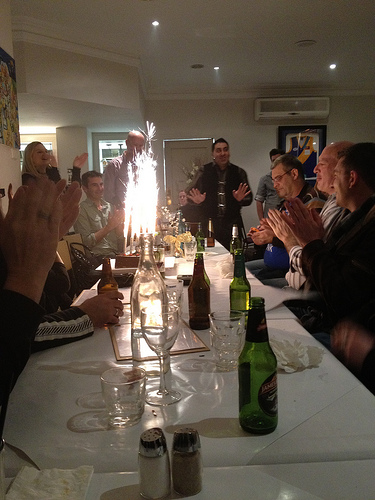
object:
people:
[73, 170, 125, 262]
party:
[2, 106, 375, 450]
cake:
[115, 249, 162, 269]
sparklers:
[119, 121, 160, 238]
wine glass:
[141, 305, 183, 407]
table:
[3, 231, 365, 496]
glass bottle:
[238, 297, 278, 434]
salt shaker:
[138, 427, 172, 499]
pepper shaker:
[171, 427, 202, 496]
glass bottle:
[188, 253, 211, 330]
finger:
[114, 308, 124, 316]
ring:
[115, 309, 119, 316]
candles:
[123, 236, 144, 256]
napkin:
[258, 339, 326, 374]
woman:
[23, 141, 88, 178]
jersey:
[285, 136, 317, 178]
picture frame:
[278, 124, 327, 183]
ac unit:
[254, 95, 330, 119]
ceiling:
[13, 2, 375, 100]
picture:
[0, 47, 21, 150]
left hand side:
[0, 4, 154, 500]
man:
[187, 138, 253, 251]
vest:
[202, 161, 239, 220]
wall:
[144, 96, 375, 138]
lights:
[152, 17, 337, 70]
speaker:
[190, 62, 204, 69]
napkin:
[6, 465, 93, 500]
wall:
[0, 0, 17, 211]